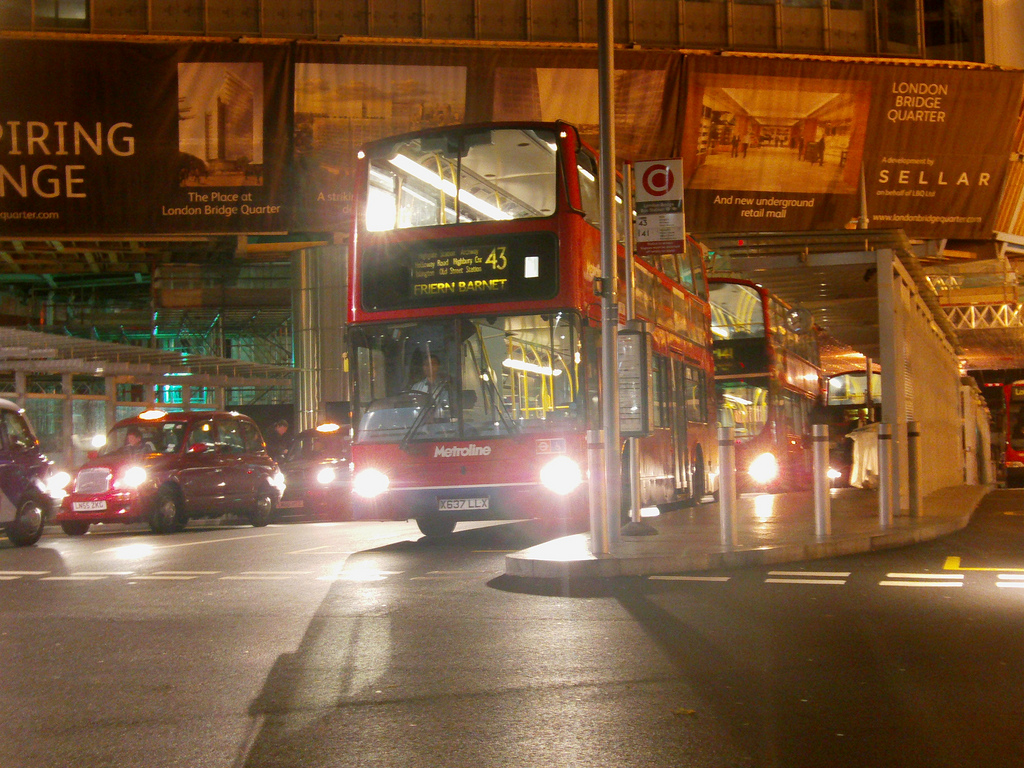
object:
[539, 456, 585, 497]
light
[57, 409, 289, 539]
bus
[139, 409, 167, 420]
light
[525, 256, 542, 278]
light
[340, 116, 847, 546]
bus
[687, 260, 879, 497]
bus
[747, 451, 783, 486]
light